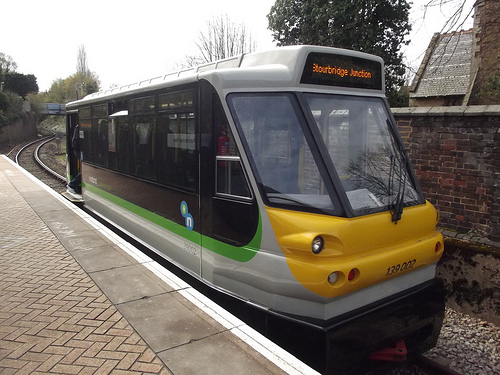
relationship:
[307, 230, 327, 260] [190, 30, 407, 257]
head light on train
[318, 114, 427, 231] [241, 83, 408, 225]
windshield wipers on windshield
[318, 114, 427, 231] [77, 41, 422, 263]
windshield wipers on train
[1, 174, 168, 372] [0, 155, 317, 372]
brick on platform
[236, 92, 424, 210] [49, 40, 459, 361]
windshield on train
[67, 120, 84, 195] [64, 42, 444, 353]
person on train